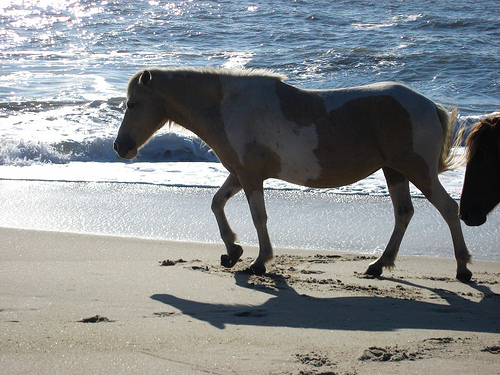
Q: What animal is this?
A: Horse.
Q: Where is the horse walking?
A: Beach.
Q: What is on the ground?
A: Sand.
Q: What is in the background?
A: Water.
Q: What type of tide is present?
A: Low tide.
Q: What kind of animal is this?
A: Horse.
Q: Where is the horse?
A: Sand.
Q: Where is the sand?
A: Beach.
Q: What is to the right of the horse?
A: Body of water.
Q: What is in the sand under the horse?
A: Hoof prints.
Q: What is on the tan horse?
A: White spots.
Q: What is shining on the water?
A: Sunrays.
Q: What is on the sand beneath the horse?
A: Shadow.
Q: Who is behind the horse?
A: Another brown horse.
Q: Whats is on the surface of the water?
A: Ripples.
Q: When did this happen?
A: During the day time.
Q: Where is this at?
A: A beach.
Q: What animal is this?
A: Horse.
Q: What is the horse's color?
A: Brown and beige.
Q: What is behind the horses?
A: Ocean.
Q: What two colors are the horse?
A: White and tan.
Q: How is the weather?
A: Sunny.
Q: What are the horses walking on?
A: Beach sand.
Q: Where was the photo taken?
A: Beach.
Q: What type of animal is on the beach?
A: Horse.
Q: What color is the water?
A: Blue.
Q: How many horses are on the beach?
A: Two.